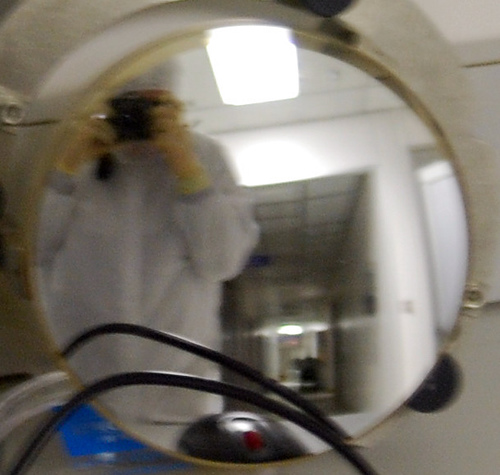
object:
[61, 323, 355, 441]
wires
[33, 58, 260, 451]
person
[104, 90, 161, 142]
camera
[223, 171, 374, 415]
hallway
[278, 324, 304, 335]
light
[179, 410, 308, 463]
mouse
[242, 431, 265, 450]
red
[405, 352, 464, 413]
circle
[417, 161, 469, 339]
white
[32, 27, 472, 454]
mirror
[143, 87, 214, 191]
gloves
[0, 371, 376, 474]
wire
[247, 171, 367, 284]
ceiling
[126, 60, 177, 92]
cap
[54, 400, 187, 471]
item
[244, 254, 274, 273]
sign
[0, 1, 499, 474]
lab